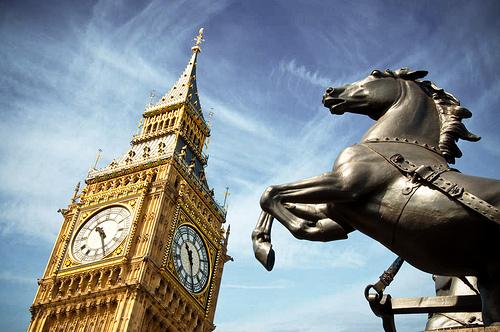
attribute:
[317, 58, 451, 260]
statue — grey, horse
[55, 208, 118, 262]
clock — white, black, big, trimmed, beige, tip, huge, 25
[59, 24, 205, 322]
tower — clock, gold, designed, ornate, pointed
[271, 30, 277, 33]
sky — blue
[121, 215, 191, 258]
building — gold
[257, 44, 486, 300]
horse — statue, black, rising, angry, beautiful, rearing, heavy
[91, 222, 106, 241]
handles — black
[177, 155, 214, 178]
steeple — black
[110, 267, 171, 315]
windows — arched